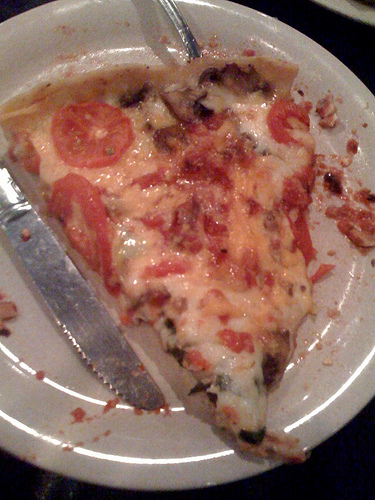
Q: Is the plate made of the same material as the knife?
A: Yes, both the plate and the knife are made of metal.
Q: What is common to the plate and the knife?
A: The material, both the plate and the knife are metallic.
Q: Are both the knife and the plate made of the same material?
A: Yes, both the knife and the plate are made of metal.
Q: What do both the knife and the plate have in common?
A: The material, both the knife and the plate are metallic.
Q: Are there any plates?
A: Yes, there is a plate.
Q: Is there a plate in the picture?
A: Yes, there is a plate.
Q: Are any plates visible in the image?
A: Yes, there is a plate.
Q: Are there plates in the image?
A: Yes, there is a plate.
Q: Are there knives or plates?
A: Yes, there is a plate.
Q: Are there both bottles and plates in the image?
A: No, there is a plate but no bottles.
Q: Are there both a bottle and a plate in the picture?
A: No, there is a plate but no bottles.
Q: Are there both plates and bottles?
A: No, there is a plate but no bottles.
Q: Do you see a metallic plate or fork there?
A: Yes, there is a metal plate.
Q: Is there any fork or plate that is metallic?
A: Yes, the plate is metallic.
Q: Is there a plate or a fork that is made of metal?
A: Yes, the plate is made of metal.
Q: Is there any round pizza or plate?
A: Yes, there is a round plate.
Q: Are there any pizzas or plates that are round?
A: Yes, the plate is round.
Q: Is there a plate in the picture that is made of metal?
A: Yes, there is a plate that is made of metal.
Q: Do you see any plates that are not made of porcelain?
A: Yes, there is a plate that is made of metal.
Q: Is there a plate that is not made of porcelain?
A: Yes, there is a plate that is made of metal.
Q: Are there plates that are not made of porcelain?
A: Yes, there is a plate that is made of metal.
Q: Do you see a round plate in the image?
A: Yes, there is a round plate.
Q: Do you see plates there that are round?
A: Yes, there is a plate that is round.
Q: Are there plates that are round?
A: Yes, there is a plate that is round.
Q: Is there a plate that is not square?
A: Yes, there is a round plate.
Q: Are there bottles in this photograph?
A: No, there are no bottles.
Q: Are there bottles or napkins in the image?
A: No, there are no bottles or napkins.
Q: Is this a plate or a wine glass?
A: This is a plate.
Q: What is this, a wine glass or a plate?
A: This is a plate.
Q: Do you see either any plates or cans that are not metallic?
A: No, there is a plate but it is metallic.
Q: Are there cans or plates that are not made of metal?
A: No, there is a plate but it is made of metal.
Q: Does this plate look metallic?
A: Yes, the plate is metallic.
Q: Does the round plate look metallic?
A: Yes, the plate is metallic.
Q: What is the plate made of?
A: The plate is made of metal.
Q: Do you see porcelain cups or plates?
A: No, there is a plate but it is metallic.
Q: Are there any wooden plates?
A: No, there is a plate but it is metallic.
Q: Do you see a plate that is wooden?
A: No, there is a plate but it is metallic.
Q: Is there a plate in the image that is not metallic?
A: No, there is a plate but it is metallic.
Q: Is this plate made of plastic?
A: No, the plate is made of metal.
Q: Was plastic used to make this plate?
A: No, the plate is made of metal.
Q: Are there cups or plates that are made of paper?
A: No, there is a plate but it is made of metal.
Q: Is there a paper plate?
A: No, there is a plate but it is made of metal.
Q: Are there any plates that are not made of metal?
A: No, there is a plate but it is made of metal.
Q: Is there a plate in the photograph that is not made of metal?
A: No, there is a plate but it is made of metal.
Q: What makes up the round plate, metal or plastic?
A: The plate is made of metal.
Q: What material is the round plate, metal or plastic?
A: The plate is made of metal.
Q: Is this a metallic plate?
A: Yes, this is a metallic plate.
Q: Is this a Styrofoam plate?
A: No, this is a metallic plate.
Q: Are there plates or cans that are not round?
A: No, there is a plate but it is round.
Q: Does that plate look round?
A: Yes, the plate is round.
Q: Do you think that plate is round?
A: Yes, the plate is round.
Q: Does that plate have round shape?
A: Yes, the plate is round.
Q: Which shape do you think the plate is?
A: The plate is round.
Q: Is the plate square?
A: No, the plate is round.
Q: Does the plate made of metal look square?
A: No, the plate is round.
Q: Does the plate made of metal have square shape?
A: No, the plate is round.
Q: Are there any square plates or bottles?
A: No, there is a plate but it is round.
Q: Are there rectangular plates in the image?
A: No, there is a plate but it is round.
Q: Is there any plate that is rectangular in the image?
A: No, there is a plate but it is round.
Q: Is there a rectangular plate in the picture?
A: No, there is a plate but it is round.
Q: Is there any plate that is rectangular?
A: No, there is a plate but it is round.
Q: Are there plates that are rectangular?
A: No, there is a plate but it is round.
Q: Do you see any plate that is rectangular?
A: No, there is a plate but it is round.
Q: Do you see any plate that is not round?
A: No, there is a plate but it is round.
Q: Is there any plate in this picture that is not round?
A: No, there is a plate but it is round.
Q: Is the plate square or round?
A: The plate is round.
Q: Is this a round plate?
A: Yes, this is a round plate.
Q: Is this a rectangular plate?
A: No, this is a round plate.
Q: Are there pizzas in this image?
A: Yes, there is a pizza.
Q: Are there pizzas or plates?
A: Yes, there is a pizza.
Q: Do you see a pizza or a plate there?
A: Yes, there is a pizza.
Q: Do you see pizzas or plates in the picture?
A: Yes, there is a pizza.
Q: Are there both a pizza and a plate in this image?
A: Yes, there are both a pizza and a plate.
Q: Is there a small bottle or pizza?
A: Yes, there is a small pizza.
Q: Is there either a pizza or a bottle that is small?
A: Yes, the pizza is small.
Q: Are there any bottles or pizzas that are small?
A: Yes, the pizza is small.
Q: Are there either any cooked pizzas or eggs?
A: Yes, there is a cooked pizza.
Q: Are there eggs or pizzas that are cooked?
A: Yes, the pizza is cooked.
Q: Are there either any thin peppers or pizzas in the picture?
A: Yes, there is a thin pizza.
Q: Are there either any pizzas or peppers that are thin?
A: Yes, the pizza is thin.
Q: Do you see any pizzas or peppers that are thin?
A: Yes, the pizza is thin.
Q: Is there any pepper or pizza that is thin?
A: Yes, the pizza is thin.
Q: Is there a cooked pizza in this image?
A: Yes, there is a cooked pizza.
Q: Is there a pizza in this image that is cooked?
A: Yes, there is a pizza that is cooked.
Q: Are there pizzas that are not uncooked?
A: Yes, there is an cooked pizza.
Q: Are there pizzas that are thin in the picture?
A: Yes, there is a thin pizza.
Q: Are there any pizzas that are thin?
A: Yes, there is a pizza that is thin.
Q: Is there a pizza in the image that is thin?
A: Yes, there is a pizza that is thin.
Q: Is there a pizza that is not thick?
A: Yes, there is a thin pizza.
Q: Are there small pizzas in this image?
A: Yes, there is a small pizza.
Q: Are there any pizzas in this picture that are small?
A: Yes, there is a pizza that is small.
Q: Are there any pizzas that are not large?
A: Yes, there is a small pizza.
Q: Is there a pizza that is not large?
A: Yes, there is a small pizza.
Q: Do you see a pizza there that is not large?
A: Yes, there is a small pizza.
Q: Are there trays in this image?
A: No, there are no trays.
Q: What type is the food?
A: The food is a pizza.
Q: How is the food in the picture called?
A: The food is a pizza.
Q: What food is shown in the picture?
A: The food is a pizza.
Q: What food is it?
A: The food is a pizza.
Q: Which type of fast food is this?
A: That is a pizza.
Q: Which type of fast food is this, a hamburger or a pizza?
A: That is a pizza.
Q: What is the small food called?
A: The food is a pizza.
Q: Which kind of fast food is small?
A: The fast food is a pizza.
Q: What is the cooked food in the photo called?
A: The food is a pizza.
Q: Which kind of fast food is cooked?
A: The fast food is a pizza.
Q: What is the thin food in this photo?
A: The food is a pizza.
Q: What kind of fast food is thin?
A: The fast food is a pizza.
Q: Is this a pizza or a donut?
A: This is a pizza.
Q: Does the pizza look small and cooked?
A: Yes, the pizza is small and cooked.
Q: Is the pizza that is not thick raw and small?
A: No, the pizza is small but cooked.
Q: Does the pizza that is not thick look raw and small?
A: No, the pizza is small but cooked.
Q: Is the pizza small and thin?
A: Yes, the pizza is small and thin.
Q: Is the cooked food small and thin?
A: Yes, the pizza is small and thin.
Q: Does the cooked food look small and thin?
A: Yes, the pizza is small and thin.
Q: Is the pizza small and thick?
A: No, the pizza is small but thin.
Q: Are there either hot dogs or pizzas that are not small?
A: No, there is a pizza but it is small.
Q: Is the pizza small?
A: Yes, the pizza is small.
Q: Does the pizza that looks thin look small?
A: Yes, the pizza is small.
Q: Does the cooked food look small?
A: Yes, the pizza is small.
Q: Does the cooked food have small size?
A: Yes, the pizza is small.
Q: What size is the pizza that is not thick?
A: The pizza is small.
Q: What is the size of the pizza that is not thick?
A: The pizza is small.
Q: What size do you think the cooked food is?
A: The pizza is small.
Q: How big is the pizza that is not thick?
A: The pizza is small.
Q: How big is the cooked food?
A: The pizza is small.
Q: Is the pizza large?
A: No, the pizza is small.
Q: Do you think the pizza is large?
A: No, the pizza is small.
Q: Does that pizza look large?
A: No, the pizza is small.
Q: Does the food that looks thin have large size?
A: No, the pizza is small.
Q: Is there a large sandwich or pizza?
A: No, there is a pizza but it is small.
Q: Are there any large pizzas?
A: No, there is a pizza but it is small.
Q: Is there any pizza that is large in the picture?
A: No, there is a pizza but it is small.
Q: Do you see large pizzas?
A: No, there is a pizza but it is small.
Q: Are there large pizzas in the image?
A: No, there is a pizza but it is small.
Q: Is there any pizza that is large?
A: No, there is a pizza but it is small.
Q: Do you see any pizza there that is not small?
A: No, there is a pizza but it is small.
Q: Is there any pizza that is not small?
A: No, there is a pizza but it is small.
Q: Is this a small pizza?
A: Yes, this is a small pizza.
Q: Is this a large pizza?
A: No, this is a small pizza.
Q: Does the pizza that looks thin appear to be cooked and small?
A: Yes, the pizza is cooked and small.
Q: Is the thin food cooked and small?
A: Yes, the pizza is cooked and small.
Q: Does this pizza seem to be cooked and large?
A: No, the pizza is cooked but small.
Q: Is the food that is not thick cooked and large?
A: No, the pizza is cooked but small.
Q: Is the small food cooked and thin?
A: Yes, the pizza is cooked and thin.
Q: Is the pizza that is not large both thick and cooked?
A: No, the pizza is cooked but thin.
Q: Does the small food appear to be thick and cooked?
A: No, the pizza is cooked but thin.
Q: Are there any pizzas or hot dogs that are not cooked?
A: No, there is a pizza but it is cooked.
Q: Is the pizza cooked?
A: Yes, the pizza is cooked.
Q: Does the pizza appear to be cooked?
A: Yes, the pizza is cooked.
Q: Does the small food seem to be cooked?
A: Yes, the pizza is cooked.